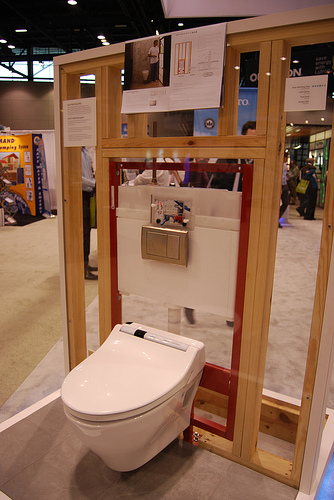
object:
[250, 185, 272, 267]
wood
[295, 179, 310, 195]
bag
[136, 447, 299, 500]
tile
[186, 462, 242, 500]
floor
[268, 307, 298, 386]
tile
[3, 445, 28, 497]
floor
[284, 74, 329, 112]
sign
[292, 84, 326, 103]
letter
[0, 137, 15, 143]
letters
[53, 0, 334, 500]
display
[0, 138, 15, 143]
letter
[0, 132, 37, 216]
sign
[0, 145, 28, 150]
letter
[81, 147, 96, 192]
shirt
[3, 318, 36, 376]
floor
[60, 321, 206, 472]
toilet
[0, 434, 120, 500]
tile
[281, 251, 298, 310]
floor